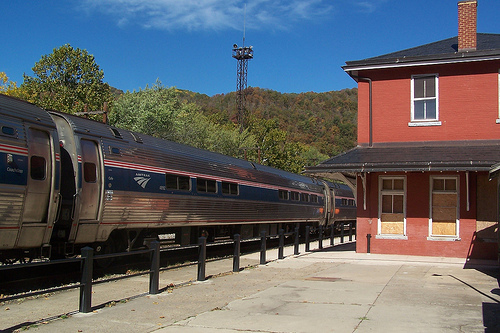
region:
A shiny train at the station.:
[0, 91, 357, 271]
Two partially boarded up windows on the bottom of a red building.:
[381, 176, 463, 242]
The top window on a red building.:
[406, 71, 441, 127]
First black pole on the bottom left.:
[76, 243, 95, 313]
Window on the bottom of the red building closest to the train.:
[378, 174, 408, 240]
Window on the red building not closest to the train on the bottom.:
[425, 171, 460, 241]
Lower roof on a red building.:
[304, 139, 499, 175]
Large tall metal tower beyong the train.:
[230, 40, 250, 146]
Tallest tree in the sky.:
[17, 44, 109, 123]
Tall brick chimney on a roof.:
[456, 1, 479, 51]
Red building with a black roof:
[321, 47, 497, 268]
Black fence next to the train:
[61, 198, 363, 320]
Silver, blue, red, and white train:
[3, 95, 355, 240]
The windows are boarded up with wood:
[371, 169, 470, 246]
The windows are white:
[374, 172, 461, 254]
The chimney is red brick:
[451, 2, 483, 59]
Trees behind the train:
[27, 34, 332, 193]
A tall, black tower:
[225, 29, 267, 140]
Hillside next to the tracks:
[54, 45, 358, 184]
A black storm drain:
[351, 72, 393, 157]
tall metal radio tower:
[221, 25, 264, 140]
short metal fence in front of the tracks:
[8, 237, 187, 318]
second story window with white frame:
[398, 65, 445, 133]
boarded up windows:
[366, 168, 467, 250]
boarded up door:
[474, 177, 495, 252]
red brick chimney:
[451, 0, 480, 53]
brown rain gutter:
[343, 58, 377, 145]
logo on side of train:
[114, 162, 161, 194]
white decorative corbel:
[351, 162, 370, 208]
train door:
[68, 112, 110, 244]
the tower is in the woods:
[199, 30, 263, 131]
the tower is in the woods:
[219, 35, 283, 180]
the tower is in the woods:
[209, 20, 336, 234]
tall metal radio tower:
[228, 2, 255, 283]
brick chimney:
[452, 0, 481, 58]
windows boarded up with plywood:
[372, 172, 463, 251]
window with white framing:
[402, 69, 452, 131]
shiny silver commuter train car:
[45, 99, 331, 269]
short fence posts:
[144, 233, 246, 298]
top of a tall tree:
[17, 40, 112, 110]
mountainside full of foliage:
[181, 14, 347, 147]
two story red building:
[301, 0, 498, 267]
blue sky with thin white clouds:
[7, 0, 425, 40]